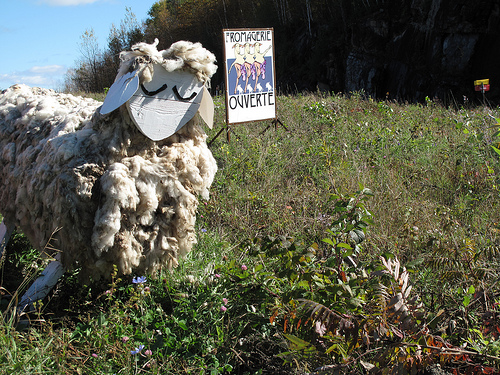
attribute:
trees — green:
[327, 9, 472, 86]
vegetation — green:
[229, 234, 496, 373]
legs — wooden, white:
[14, 254, 63, 321]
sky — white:
[0, 0, 43, 36]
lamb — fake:
[3, 36, 218, 306]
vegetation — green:
[0, 93, 499, 373]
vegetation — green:
[202, 207, 440, 332]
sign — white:
[220, 23, 278, 123]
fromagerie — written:
[220, 30, 275, 42]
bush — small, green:
[304, 108, 477, 257]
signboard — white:
[221, 23, 295, 135]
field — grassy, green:
[9, 86, 493, 366]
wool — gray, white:
[1, 28, 213, 271]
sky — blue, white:
[0, 0, 159, 93]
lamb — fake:
[8, 32, 241, 299]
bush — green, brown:
[295, 184, 440, 362]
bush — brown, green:
[136, 190, 317, 367]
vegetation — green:
[231, 136, 498, 370]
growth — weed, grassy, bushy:
[1, 190, 498, 374]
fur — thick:
[22, 149, 146, 218]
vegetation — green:
[61, 310, 321, 365]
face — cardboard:
[123, 65, 213, 142]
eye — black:
[172, 80, 197, 102]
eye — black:
[136, 80, 168, 94]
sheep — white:
[0, 35, 222, 311]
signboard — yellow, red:
[221, 28, 295, 126]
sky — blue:
[22, 8, 62, 54]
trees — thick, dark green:
[67, 1, 498, 107]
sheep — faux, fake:
[0, 38, 217, 278]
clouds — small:
[1, 0, 157, 93]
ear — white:
[100, 65, 140, 115]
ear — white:
[200, 86, 216, 129]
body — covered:
[0, 30, 233, 315]